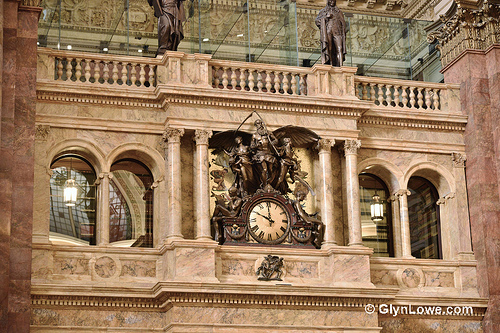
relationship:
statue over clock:
[289, 0, 379, 90] [225, 188, 363, 268]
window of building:
[354, 162, 403, 259] [2, 1, 498, 331]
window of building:
[349, 157, 408, 262] [18, 13, 487, 325]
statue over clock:
[145, 0, 187, 53] [241, 195, 294, 241]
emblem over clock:
[255, 245, 287, 284] [252, 194, 290, 244]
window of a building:
[69, 157, 191, 242] [46, 60, 467, 325]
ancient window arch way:
[109, 121, 164, 304] [42, 139, 106, 249]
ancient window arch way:
[101, 141, 166, 249] [120, 193, 194, 333]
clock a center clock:
[194, 117, 334, 258] [206, 118, 323, 251]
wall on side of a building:
[183, 142, 235, 239] [18, 98, 495, 333]